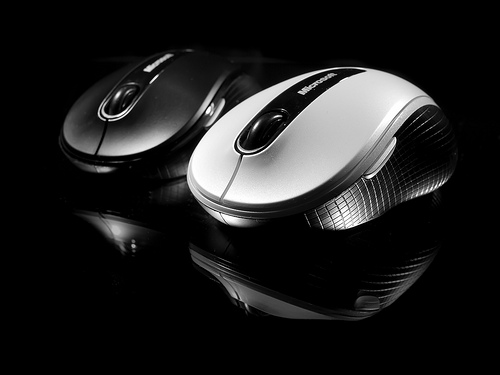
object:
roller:
[244, 108, 288, 146]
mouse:
[184, 66, 460, 236]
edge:
[325, 94, 439, 190]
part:
[111, 84, 140, 106]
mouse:
[54, 47, 268, 181]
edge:
[96, 118, 196, 171]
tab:
[361, 135, 398, 182]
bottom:
[196, 205, 444, 274]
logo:
[293, 70, 341, 98]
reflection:
[185, 223, 446, 322]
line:
[216, 150, 252, 201]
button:
[360, 136, 398, 182]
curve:
[302, 104, 460, 235]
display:
[57, 36, 458, 234]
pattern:
[296, 104, 458, 234]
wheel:
[245, 113, 286, 144]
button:
[201, 101, 216, 120]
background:
[0, 2, 499, 375]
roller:
[105, 84, 138, 112]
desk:
[0, 0, 498, 374]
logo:
[143, 51, 177, 74]